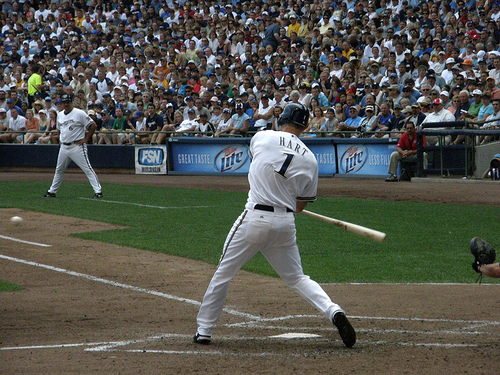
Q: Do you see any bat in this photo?
A: Yes, there is a bat.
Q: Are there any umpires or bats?
A: Yes, there is a bat.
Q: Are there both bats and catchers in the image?
A: Yes, there are both a bat and a catcher.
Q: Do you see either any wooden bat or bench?
A: Yes, there is a wood bat.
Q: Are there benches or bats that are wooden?
A: Yes, the bat is wooden.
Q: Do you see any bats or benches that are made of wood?
A: Yes, the bat is made of wood.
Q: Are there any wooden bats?
A: Yes, there is a wood bat.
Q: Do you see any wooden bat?
A: Yes, there is a wood bat.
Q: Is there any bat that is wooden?
A: Yes, there is a bat that is wooden.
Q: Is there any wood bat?
A: Yes, there is a bat that is made of wood.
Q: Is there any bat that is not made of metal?
A: Yes, there is a bat that is made of wood.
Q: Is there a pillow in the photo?
A: No, there are no pillows.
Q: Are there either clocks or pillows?
A: No, there are no pillows or clocks.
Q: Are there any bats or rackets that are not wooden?
A: No, there is a bat but it is wooden.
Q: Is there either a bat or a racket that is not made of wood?
A: No, there is a bat but it is made of wood.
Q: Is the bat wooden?
A: Yes, the bat is wooden.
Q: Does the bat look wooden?
A: Yes, the bat is wooden.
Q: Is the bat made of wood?
A: Yes, the bat is made of wood.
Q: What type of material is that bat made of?
A: The bat is made of wood.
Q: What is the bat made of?
A: The bat is made of wood.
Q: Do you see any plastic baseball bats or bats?
A: No, there is a bat but it is wooden.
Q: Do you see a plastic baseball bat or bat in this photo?
A: No, there is a bat but it is wooden.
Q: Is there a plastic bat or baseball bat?
A: No, there is a bat but it is wooden.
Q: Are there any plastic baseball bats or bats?
A: No, there is a bat but it is wooden.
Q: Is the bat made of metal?
A: No, the bat is made of wood.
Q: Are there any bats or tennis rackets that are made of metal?
A: No, there is a bat but it is made of wood.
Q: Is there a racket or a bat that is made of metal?
A: No, there is a bat but it is made of wood.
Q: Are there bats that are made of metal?
A: No, there is a bat but it is made of wood.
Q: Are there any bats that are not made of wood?
A: No, there is a bat but it is made of wood.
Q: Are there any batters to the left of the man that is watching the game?
A: Yes, there is a batter to the left of the man.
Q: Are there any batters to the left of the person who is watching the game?
A: Yes, there is a batter to the left of the man.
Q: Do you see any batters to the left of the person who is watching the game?
A: Yes, there is a batter to the left of the man.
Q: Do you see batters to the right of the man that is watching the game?
A: No, the batter is to the left of the man.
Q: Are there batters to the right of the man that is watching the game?
A: No, the batter is to the left of the man.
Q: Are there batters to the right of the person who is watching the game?
A: No, the batter is to the left of the man.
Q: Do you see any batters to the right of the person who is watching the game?
A: No, the batter is to the left of the man.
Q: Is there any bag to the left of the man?
A: No, there is a batter to the left of the man.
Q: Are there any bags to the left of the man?
A: No, there is a batter to the left of the man.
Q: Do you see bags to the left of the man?
A: No, there is a batter to the left of the man.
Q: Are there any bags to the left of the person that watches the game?
A: No, there is a batter to the left of the man.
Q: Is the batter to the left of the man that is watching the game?
A: Yes, the batter is to the left of the man.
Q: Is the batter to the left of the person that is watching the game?
A: Yes, the batter is to the left of the man.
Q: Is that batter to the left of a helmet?
A: No, the batter is to the left of the man.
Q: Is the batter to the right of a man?
A: No, the batter is to the left of a man.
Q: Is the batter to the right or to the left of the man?
A: The batter is to the left of the man.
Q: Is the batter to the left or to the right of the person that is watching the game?
A: The batter is to the left of the man.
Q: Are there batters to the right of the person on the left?
A: Yes, there is a batter to the right of the person.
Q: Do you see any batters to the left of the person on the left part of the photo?
A: No, the batter is to the right of the person.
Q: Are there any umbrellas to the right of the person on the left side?
A: No, there is a batter to the right of the person.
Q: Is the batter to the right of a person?
A: Yes, the batter is to the right of a person.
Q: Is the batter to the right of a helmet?
A: No, the batter is to the right of a person.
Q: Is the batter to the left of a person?
A: No, the batter is to the right of a person.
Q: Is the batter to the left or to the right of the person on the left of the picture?
A: The batter is to the right of the person.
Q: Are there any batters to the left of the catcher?
A: Yes, there is a batter to the left of the catcher.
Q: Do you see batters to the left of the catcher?
A: Yes, there is a batter to the left of the catcher.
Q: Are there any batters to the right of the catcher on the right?
A: No, the batter is to the left of the catcher.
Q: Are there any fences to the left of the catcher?
A: No, there is a batter to the left of the catcher.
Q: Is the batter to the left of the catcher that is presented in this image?
A: Yes, the batter is to the left of the catcher.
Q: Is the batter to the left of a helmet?
A: No, the batter is to the left of the catcher.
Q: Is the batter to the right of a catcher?
A: No, the batter is to the left of a catcher.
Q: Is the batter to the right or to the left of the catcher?
A: The batter is to the left of the catcher.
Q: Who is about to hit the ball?
A: The batter is about to hit the ball.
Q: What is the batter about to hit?
A: The batter is about to hit the ball.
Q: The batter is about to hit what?
A: The batter is about to hit the ball.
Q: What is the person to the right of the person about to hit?
A: The batter is about to hit the ball.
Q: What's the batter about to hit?
A: The batter is about to hit the ball.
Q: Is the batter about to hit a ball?
A: Yes, the batter is about to hit a ball.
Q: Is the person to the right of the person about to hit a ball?
A: Yes, the batter is about to hit a ball.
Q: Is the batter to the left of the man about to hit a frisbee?
A: No, the batter is about to hit a ball.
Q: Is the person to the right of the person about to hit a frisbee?
A: No, the batter is about to hit a ball.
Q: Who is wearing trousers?
A: The batter is wearing trousers.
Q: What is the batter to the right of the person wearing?
A: The batter is wearing trousers.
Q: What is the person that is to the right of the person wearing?
A: The batter is wearing trousers.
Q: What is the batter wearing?
A: The batter is wearing trousers.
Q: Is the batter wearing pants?
A: Yes, the batter is wearing pants.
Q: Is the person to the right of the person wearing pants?
A: Yes, the batter is wearing pants.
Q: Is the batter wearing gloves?
A: No, the batter is wearing pants.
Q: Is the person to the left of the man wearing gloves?
A: No, the batter is wearing pants.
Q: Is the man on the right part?
A: Yes, the man is on the right of the image.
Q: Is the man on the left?
A: No, the man is on the right of the image.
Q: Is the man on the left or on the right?
A: The man is on the right of the image.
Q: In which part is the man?
A: The man is on the right of the image.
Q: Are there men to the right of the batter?
A: Yes, there is a man to the right of the batter.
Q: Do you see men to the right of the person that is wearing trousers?
A: Yes, there is a man to the right of the batter.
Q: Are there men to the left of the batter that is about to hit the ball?
A: No, the man is to the right of the batter.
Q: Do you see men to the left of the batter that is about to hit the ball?
A: No, the man is to the right of the batter.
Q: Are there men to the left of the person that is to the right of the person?
A: No, the man is to the right of the batter.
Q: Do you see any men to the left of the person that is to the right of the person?
A: No, the man is to the right of the batter.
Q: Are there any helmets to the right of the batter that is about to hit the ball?
A: No, there is a man to the right of the batter.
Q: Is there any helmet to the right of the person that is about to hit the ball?
A: No, there is a man to the right of the batter.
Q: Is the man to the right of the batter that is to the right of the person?
A: Yes, the man is to the right of the batter.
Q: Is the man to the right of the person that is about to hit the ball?
A: Yes, the man is to the right of the batter.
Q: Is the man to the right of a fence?
A: No, the man is to the right of the batter.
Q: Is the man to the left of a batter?
A: No, the man is to the right of a batter.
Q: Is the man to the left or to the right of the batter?
A: The man is to the right of the batter.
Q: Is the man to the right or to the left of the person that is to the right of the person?
A: The man is to the right of the batter.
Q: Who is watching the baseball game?
A: The man is watching the game.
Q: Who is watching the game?
A: The man is watching the game.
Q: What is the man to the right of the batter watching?
A: The man is watching the game.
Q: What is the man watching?
A: The man is watching the game.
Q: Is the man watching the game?
A: Yes, the man is watching the game.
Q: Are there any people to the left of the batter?
A: Yes, there is a person to the left of the batter.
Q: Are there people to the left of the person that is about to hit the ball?
A: Yes, there is a person to the left of the batter.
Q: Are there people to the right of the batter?
A: No, the person is to the left of the batter.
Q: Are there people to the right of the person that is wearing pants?
A: No, the person is to the left of the batter.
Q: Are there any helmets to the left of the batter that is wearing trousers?
A: No, there is a person to the left of the batter.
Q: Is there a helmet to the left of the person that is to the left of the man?
A: No, there is a person to the left of the batter.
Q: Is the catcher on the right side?
A: Yes, the catcher is on the right of the image.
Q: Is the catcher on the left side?
A: No, the catcher is on the right of the image.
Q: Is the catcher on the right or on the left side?
A: The catcher is on the right of the image.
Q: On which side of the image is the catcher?
A: The catcher is on the right of the image.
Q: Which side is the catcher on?
A: The catcher is on the right of the image.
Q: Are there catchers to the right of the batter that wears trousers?
A: Yes, there is a catcher to the right of the batter.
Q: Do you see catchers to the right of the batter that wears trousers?
A: Yes, there is a catcher to the right of the batter.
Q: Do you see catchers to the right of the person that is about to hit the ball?
A: Yes, there is a catcher to the right of the batter.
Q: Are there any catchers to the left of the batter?
A: No, the catcher is to the right of the batter.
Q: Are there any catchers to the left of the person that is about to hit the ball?
A: No, the catcher is to the right of the batter.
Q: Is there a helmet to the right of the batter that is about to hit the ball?
A: No, there is a catcher to the right of the batter.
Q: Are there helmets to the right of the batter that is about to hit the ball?
A: No, there is a catcher to the right of the batter.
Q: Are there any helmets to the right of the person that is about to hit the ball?
A: No, there is a catcher to the right of the batter.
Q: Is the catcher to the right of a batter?
A: Yes, the catcher is to the right of a batter.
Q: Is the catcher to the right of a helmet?
A: No, the catcher is to the right of a batter.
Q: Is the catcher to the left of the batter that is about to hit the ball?
A: No, the catcher is to the right of the batter.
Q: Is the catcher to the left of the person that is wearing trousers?
A: No, the catcher is to the right of the batter.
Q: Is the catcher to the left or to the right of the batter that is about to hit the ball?
A: The catcher is to the right of the batter.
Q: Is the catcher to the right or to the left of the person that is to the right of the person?
A: The catcher is to the right of the batter.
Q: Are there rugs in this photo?
A: No, there are no rugs.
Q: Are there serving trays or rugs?
A: No, there are no rugs or serving trays.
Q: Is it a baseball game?
A: Yes, that is a baseball game.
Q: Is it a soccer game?
A: No, that is a baseball game.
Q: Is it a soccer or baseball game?
A: That is a baseball game.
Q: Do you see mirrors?
A: No, there are no mirrors.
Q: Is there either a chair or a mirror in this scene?
A: No, there are no mirrors or chairs.